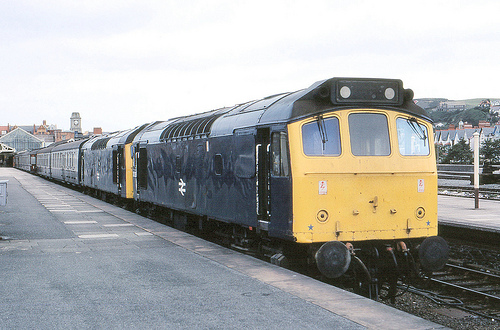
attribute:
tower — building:
[64, 108, 88, 135]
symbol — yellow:
[178, 177, 185, 195]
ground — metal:
[418, 139, 468, 164]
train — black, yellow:
[8, 75, 450, 302]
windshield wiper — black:
[410, 116, 429, 145]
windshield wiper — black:
[315, 112, 329, 144]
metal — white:
[1, 138, 22, 152]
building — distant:
[5, 111, 55, 164]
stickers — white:
[317, 179, 433, 192]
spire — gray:
[64, 104, 84, 139]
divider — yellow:
[123, 140, 138, 200]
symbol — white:
[165, 173, 193, 205]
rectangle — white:
[105, 223, 151, 237]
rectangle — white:
[61, 220, 117, 237]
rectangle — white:
[50, 210, 96, 220]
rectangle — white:
[42, 206, 78, 213]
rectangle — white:
[35, 196, 71, 206]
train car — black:
[131, 64, 443, 278]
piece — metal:
[1, 140, 17, 154]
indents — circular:
[313, 206, 427, 220]